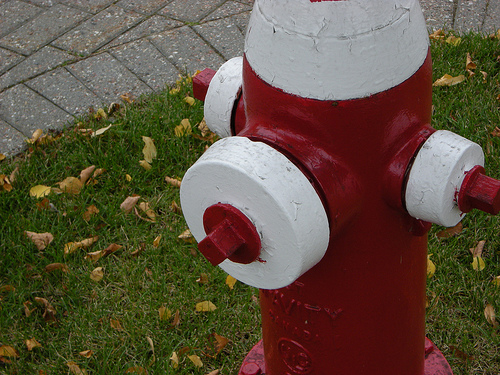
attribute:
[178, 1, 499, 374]
fire hydrant — red, white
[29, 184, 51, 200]
leaf — yellow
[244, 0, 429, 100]
top — white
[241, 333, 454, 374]
base — circular, red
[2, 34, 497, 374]
grass — green, tall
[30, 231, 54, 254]
leaf — brown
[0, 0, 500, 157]
sidewalk — paved, brick, gray, white, gray blocks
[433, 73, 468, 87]
leaf — yellow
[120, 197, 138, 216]
leaf — brown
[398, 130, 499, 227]
side part — white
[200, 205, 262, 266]
bolt — red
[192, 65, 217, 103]
bolt — red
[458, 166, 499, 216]
bolt — red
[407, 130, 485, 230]
base — white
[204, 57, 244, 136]
base — white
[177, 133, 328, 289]
base — white, metal